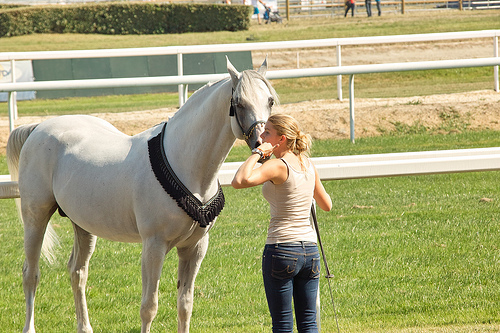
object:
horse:
[6, 53, 278, 332]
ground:
[0, 75, 495, 333]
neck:
[158, 77, 234, 196]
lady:
[231, 113, 333, 333]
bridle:
[147, 120, 224, 227]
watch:
[251, 148, 263, 154]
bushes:
[0, 0, 255, 33]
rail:
[0, 32, 500, 141]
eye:
[267, 97, 275, 108]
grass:
[0, 125, 497, 333]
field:
[1, 126, 496, 330]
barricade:
[0, 30, 498, 144]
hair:
[267, 114, 313, 158]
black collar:
[147, 119, 226, 228]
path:
[0, 147, 500, 196]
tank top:
[260, 159, 317, 244]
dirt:
[347, 106, 438, 131]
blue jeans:
[261, 243, 324, 333]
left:
[0, 5, 63, 331]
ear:
[257, 53, 268, 78]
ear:
[224, 54, 239, 83]